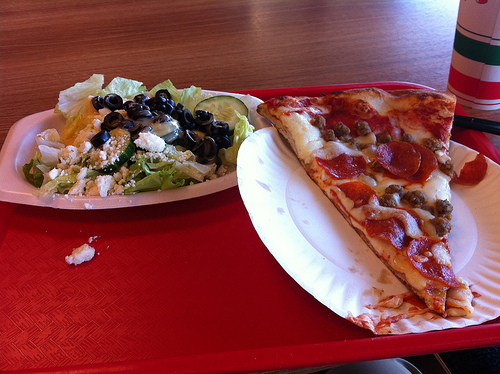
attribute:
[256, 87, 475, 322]
slice of pizza — triangular shaped, pictured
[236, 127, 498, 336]
plate — white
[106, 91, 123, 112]
olive — black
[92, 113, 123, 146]
two olives — pictured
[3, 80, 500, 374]
tray — red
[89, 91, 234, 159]
olives — black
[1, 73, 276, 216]
plate of salad — pictured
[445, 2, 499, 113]
cup — italian colored, white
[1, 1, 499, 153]
table — wooden, red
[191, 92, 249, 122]
cucumber — pictured, green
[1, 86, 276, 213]
tray — white, pink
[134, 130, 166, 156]
cheese — white